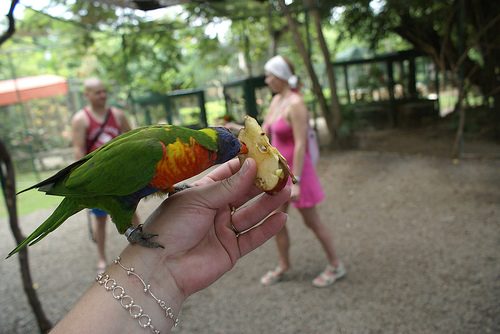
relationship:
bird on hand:
[28, 107, 299, 260] [26, 136, 312, 325]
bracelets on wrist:
[111, 251, 186, 328] [113, 213, 199, 305]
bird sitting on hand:
[0, 107, 297, 332] [144, 154, 288, 304]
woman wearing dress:
[248, 49, 352, 294] [262, 89, 327, 211]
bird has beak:
[28, 65, 235, 260] [238, 139, 251, 155]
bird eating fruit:
[28, 107, 299, 260] [234, 114, 291, 193]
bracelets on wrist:
[111, 251, 186, 328] [81, 235, 182, 332]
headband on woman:
[253, 60, 328, 104] [225, 59, 397, 311]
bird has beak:
[28, 107, 299, 260] [238, 139, 251, 155]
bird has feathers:
[28, 107, 299, 260] [20, 122, 216, 195]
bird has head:
[28, 107, 299, 260] [213, 126, 248, 165]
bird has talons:
[28, 107, 299, 260] [120, 225, 168, 248]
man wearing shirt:
[70, 74, 142, 275] [83, 107, 120, 154]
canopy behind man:
[0, 73, 67, 105] [70, 74, 142, 275]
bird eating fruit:
[28, 107, 299, 260] [234, 89, 291, 236]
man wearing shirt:
[70, 74, 142, 275] [73, 105, 148, 178]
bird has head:
[28, 107, 299, 260] [211, 125, 246, 160]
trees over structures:
[347, 0, 494, 118] [328, 47, 441, 124]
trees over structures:
[347, 0, 494, 118] [222, 68, 275, 125]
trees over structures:
[347, 0, 494, 118] [130, 87, 208, 131]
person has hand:
[258, 56, 347, 288] [44, 151, 291, 332]